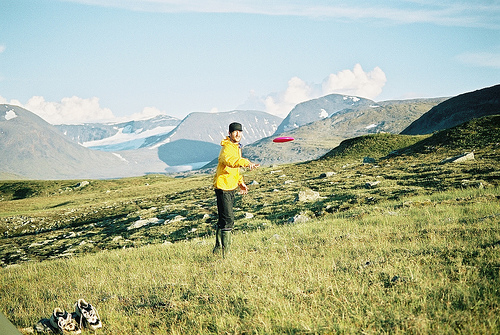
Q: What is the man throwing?
A: A frisbee.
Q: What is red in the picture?
A: A frisbee.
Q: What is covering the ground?
A: Grass.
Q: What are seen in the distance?
A: Hills.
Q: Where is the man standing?
A: A mountain.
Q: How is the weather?
A: Sunny.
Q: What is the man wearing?
A: A yellow jacket.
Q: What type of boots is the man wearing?
A: Rain boots.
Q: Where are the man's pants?
A: Tucked into boots.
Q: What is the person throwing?
A: A frisbee.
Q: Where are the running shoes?
A: In the grass.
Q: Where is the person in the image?
A: The center.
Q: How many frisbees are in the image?
A: One.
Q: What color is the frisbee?
A: Red.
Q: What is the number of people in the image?
A: One.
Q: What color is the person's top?
A: Yellow.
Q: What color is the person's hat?
A: Black.